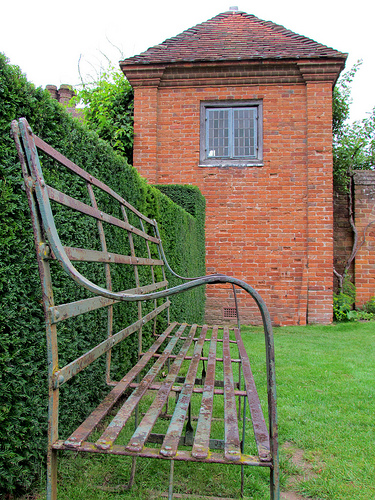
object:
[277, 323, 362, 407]
grass area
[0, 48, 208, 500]
hedge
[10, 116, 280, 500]
bench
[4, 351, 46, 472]
green hedge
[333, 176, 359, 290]
wine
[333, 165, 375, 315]
brick wall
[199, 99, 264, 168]
window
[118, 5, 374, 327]
building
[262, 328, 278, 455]
slat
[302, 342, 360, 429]
grass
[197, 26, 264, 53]
red tile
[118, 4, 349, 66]
roof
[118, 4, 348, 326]
building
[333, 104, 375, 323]
tree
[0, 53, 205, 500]
hedge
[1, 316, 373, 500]
grass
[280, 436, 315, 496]
patch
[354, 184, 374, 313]
wall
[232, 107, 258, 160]
window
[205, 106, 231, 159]
window